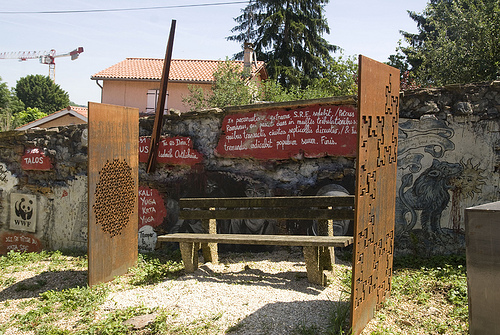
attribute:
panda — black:
[11, 195, 36, 220]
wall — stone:
[406, 95, 459, 241]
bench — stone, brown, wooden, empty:
[179, 196, 326, 275]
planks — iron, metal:
[335, 46, 417, 323]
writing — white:
[225, 112, 324, 146]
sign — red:
[23, 154, 53, 171]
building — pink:
[103, 53, 219, 111]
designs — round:
[98, 156, 137, 236]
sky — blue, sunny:
[23, 12, 68, 40]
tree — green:
[242, 8, 320, 65]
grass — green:
[418, 259, 451, 288]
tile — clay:
[143, 60, 155, 70]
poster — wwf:
[7, 187, 42, 237]